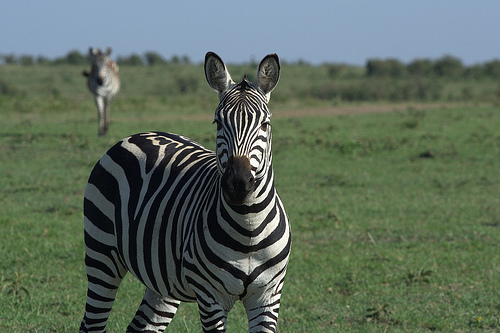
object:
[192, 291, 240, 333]
legs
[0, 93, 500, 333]
grass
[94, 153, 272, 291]
body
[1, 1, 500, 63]
sky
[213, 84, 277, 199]
face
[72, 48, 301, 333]
zebra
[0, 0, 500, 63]
clouds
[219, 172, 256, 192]
nose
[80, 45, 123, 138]
zebra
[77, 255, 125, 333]
back legs